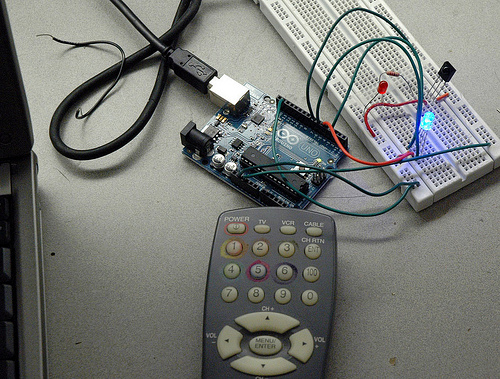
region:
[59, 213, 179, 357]
floor is grey in color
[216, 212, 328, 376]
the keyboard is grey in color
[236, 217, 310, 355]
remote has white buttons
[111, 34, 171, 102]
cable is black in color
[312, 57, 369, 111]
cable is green in color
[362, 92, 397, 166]
cable is red in color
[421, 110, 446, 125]
light is green in color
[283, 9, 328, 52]
motherbody is white in color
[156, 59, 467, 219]
A microcontroller programmed to turn on an led light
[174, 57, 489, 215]
A microcontroller programmed to turn on an led light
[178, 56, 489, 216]
A microcontroller programmed to turn on an led light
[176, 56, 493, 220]
A microcontroller programmed to turn on an led light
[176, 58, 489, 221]
A microcontroller programmed to turn on an led light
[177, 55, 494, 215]
A microcontroller programmed to turn on an led light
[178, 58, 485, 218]
A microcontroller programmed to turn on an led light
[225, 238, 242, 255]
The number is black.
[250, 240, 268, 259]
The number is black.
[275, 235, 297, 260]
The number is black.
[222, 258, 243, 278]
The number is black.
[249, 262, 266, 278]
The number is black.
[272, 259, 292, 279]
The number is black.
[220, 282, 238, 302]
The number is black.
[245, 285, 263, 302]
The number is black.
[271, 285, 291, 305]
The number is black.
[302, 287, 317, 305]
The number is black.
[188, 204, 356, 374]
a tv remote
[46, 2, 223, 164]
a long cord hooked to an electronic part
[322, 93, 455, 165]
two red wires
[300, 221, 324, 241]
a button on the remote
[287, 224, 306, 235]
a button on the remote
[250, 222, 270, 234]
a button on the remote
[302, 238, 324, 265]
a button on the remote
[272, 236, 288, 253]
a button on the remote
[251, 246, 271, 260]
a button on the remote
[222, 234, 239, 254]
a button on the remote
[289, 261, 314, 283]
a button on the remote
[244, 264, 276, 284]
a button on the remote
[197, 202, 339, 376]
remote control on a surface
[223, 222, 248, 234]
power button on a remote control